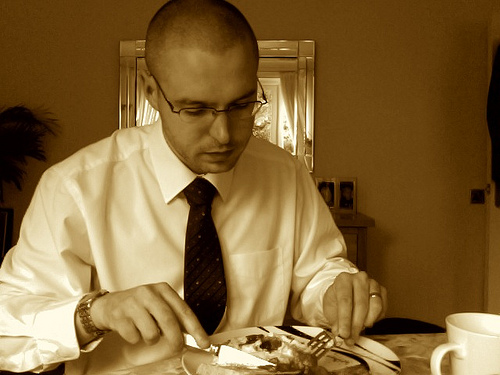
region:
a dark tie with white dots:
[186, 176, 252, 356]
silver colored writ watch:
[78, 279, 133, 355]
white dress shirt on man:
[68, 161, 361, 333]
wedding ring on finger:
[365, 276, 391, 318]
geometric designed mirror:
[112, 24, 335, 136]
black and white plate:
[252, 304, 375, 372]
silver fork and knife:
[212, 339, 390, 373]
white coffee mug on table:
[434, 300, 495, 370]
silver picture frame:
[310, 167, 372, 232]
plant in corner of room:
[22, 88, 57, 196]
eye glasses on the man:
[137, 61, 271, 131]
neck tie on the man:
[180, 178, 225, 340]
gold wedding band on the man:
[366, 287, 383, 302]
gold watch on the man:
[73, 286, 108, 341]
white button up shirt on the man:
[0, 140, 402, 370]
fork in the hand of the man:
[298, 321, 348, 359]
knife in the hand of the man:
[162, 337, 288, 369]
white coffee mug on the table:
[423, 303, 498, 373]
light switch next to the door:
[466, 186, 488, 211]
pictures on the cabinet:
[304, 172, 359, 223]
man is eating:
[2, 0, 393, 373]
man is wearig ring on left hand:
[368, 290, 383, 300]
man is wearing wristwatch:
[76, 286, 111, 339]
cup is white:
[427, 312, 498, 374]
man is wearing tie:
[182, 173, 231, 341]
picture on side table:
[316, 174, 363, 216]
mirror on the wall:
[118, 36, 315, 169]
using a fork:
[306, 323, 336, 363]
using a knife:
[179, 328, 277, 368]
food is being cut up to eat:
[176, 264, 404, 374]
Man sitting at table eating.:
[3, 16, 403, 372]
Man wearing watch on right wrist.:
[76, 286, 111, 337]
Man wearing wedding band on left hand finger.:
[367, 285, 383, 302]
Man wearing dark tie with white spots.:
[174, 176, 236, 338]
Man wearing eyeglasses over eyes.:
[156, 77, 274, 129]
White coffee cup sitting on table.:
[428, 303, 499, 373]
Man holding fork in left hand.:
[306, 267, 391, 362]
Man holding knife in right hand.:
[113, 281, 278, 373]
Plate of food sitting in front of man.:
[177, 321, 402, 373]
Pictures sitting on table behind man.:
[311, 170, 366, 217]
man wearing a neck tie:
[184, 180, 230, 343]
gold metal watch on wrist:
[74, 287, 105, 339]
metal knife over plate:
[183, 333, 273, 366]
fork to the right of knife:
[306, 323, 338, 359]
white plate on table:
[179, 321, 400, 373]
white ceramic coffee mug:
[427, 310, 499, 372]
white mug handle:
[428, 340, 460, 374]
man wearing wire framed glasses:
[147, 65, 267, 120]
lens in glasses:
[180, 108, 214, 125]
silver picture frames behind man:
[311, 175, 340, 215]